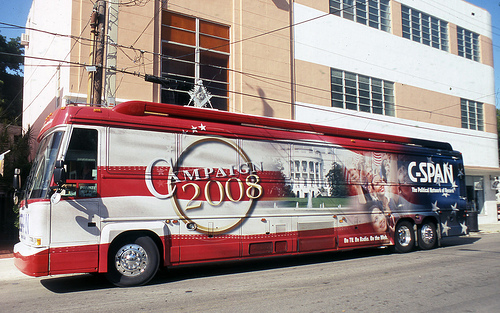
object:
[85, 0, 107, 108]
pole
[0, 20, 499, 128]
wires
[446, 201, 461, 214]
star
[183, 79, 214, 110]
symbol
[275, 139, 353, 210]
image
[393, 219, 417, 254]
tire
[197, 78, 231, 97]
window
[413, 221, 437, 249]
tire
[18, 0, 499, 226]
building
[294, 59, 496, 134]
stripe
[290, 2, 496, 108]
stripe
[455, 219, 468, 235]
star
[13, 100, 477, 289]
bus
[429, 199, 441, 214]
star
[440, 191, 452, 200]
star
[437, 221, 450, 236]
star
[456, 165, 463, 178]
star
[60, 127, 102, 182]
window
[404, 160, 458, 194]
sign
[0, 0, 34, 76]
blue sky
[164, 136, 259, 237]
circle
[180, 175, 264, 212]
2008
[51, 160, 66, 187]
mirrors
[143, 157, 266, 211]
campaign 2008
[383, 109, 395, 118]
window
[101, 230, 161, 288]
tire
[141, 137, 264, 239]
sign